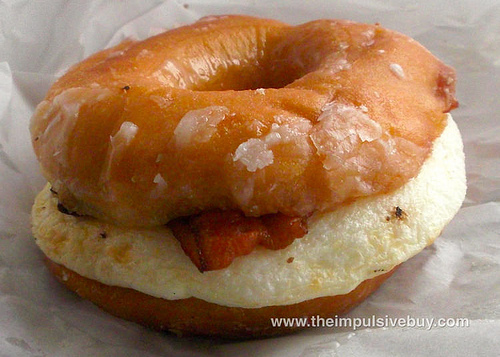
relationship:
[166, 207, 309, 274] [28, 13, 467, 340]
bacon on sandwich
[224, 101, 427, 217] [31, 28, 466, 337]
glaze on doughnut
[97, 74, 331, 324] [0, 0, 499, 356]
sandwich on food wrapper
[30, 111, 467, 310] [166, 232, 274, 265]
cooked egg between bacon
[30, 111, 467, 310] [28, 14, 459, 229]
cooked egg between donut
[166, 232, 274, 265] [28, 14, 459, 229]
bacon between donut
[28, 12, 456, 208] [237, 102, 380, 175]
donut with glaze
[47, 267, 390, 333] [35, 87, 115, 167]
donut with glaze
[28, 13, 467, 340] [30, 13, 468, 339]
sandwich on a donut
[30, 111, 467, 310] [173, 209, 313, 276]
cooked egg fried with bacon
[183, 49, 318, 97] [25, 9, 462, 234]
hole in donut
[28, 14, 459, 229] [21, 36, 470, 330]
donut on sandwich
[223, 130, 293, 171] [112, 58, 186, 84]
glaze on donut